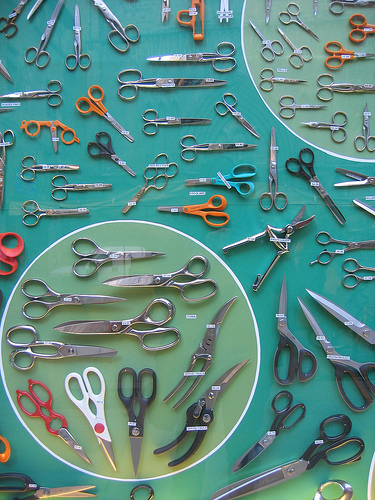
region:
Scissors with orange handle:
[76, 83, 134, 141]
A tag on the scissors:
[117, 159, 127, 165]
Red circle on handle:
[94, 421, 104, 433]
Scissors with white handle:
[65, 365, 115, 470]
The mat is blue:
[0, 0, 372, 498]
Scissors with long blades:
[211, 413, 363, 498]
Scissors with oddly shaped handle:
[16, 378, 91, 463]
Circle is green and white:
[0, 221, 260, 481]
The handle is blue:
[212, 162, 257, 198]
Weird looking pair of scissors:
[22, 119, 79, 153]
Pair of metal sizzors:
[53, 314, 185, 349]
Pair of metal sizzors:
[100, 262, 223, 298]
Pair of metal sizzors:
[66, 236, 171, 281]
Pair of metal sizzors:
[18, 278, 120, 317]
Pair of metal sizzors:
[8, 323, 105, 371]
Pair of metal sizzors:
[17, 186, 97, 221]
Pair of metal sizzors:
[34, 177, 117, 206]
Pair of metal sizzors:
[18, 154, 87, 184]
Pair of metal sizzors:
[219, 201, 329, 285]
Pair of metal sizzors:
[270, 283, 330, 416]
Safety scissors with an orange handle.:
[153, 192, 231, 234]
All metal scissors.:
[113, 42, 263, 106]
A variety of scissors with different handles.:
[17, 51, 259, 222]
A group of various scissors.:
[0, 235, 250, 466]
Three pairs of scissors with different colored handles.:
[9, 367, 162, 470]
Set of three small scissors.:
[247, 19, 312, 88]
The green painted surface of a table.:
[222, 321, 254, 356]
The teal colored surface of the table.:
[156, 91, 203, 111]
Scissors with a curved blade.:
[151, 296, 247, 473]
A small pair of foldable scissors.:
[18, 115, 83, 154]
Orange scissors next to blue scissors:
[148, 192, 227, 227]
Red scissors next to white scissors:
[13, 377, 93, 467]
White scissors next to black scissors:
[65, 366, 118, 472]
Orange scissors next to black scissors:
[71, 84, 139, 144]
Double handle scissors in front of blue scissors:
[113, 153, 179, 215]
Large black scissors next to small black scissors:
[201, 408, 370, 498]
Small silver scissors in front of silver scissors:
[214, 90, 262, 141]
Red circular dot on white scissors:
[93, 421, 104, 433]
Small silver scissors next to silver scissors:
[49, 174, 113, 202]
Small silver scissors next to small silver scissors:
[255, 66, 308, 96]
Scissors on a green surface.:
[0, 0, 370, 496]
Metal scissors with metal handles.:
[3, 322, 113, 369]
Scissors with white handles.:
[60, 365, 120, 470]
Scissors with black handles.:
[116, 366, 157, 477]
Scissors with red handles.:
[14, 376, 91, 467]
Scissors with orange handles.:
[72, 82, 137, 145]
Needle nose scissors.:
[298, 108, 346, 142]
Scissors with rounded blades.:
[75, 85, 139, 147]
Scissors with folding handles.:
[15, 115, 76, 150]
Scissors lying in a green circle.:
[0, 217, 260, 480]